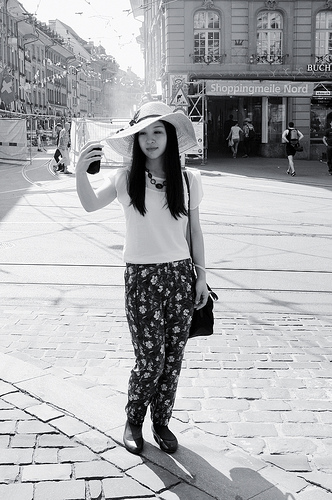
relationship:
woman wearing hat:
[76, 105, 211, 456] [105, 103, 197, 160]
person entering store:
[227, 122, 242, 153] [139, 0, 327, 159]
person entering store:
[242, 117, 258, 154] [139, 0, 327, 159]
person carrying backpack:
[281, 124, 304, 176] [291, 130, 298, 141]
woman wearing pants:
[76, 105, 211, 456] [125, 258, 196, 430]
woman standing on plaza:
[76, 105, 211, 456] [3, 156, 331, 499]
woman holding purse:
[76, 105, 211, 456] [184, 292, 215, 339]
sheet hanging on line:
[68, 120, 132, 174] [0, 109, 137, 123]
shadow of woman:
[129, 438, 295, 500] [76, 105, 211, 456]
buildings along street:
[1, 2, 143, 151] [0, 149, 57, 172]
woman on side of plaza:
[76, 105, 211, 456] [3, 156, 331, 499]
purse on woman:
[184, 292, 215, 339] [76, 105, 211, 456]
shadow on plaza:
[129, 438, 295, 500] [3, 156, 331, 499]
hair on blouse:
[128, 123, 188, 221] [119, 170, 198, 266]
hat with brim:
[105, 103, 197, 160] [106, 111, 196, 160]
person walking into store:
[227, 122, 242, 153] [139, 0, 327, 159]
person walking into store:
[242, 117, 258, 154] [139, 0, 327, 159]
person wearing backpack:
[281, 124, 304, 176] [291, 130, 298, 141]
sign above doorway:
[204, 82, 317, 98] [205, 96, 262, 162]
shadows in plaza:
[0, 261, 124, 288] [3, 156, 331, 499]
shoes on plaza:
[124, 422, 177, 453] [3, 156, 331, 499]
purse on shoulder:
[184, 292, 215, 339] [179, 172, 198, 206]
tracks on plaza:
[204, 265, 331, 296] [3, 156, 331, 499]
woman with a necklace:
[76, 105, 211, 456] [146, 164, 168, 190]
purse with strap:
[184, 292, 215, 339] [182, 171, 196, 281]